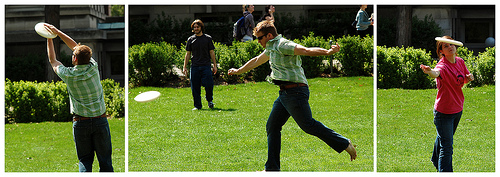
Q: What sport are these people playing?
A: Frisbee.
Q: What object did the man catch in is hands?
A: Frisbee.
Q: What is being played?
A: Frisbee.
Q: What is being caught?
A: Frisbee.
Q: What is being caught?
A: Frisbee.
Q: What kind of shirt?
A: Green.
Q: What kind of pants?
A: Jeans.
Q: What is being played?
A: Frisbee.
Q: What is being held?
A: Frisbee.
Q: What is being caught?
A: Frisbee.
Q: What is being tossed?
A: Frisbee.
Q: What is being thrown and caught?
A: A frisbee.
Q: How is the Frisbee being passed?
A: The Frisbee is being thrown.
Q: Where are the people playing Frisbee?
A: In a park.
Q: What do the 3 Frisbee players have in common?
A: All 3 players are wearing blue jeans.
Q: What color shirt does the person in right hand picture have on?
A: Pink.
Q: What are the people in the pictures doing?
A: Playing frisbee.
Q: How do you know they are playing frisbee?
A: They are holding frisbees.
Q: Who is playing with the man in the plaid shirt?
A: Man in grey shirt.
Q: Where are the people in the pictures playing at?
A: On the grass.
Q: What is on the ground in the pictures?
A: Grass.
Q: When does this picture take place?
A: Daytime.